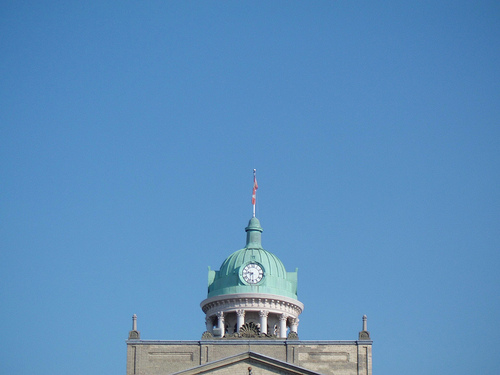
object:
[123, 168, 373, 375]
front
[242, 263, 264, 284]
clock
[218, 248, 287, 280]
dome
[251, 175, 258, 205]
flag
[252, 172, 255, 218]
pole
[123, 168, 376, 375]
building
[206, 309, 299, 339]
columns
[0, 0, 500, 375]
sky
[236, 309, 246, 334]
pillar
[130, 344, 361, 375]
wall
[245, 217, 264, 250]
roof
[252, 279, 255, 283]
numbers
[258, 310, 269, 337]
pillars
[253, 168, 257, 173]
ball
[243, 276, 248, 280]
roman numerals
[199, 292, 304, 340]
base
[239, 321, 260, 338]
design